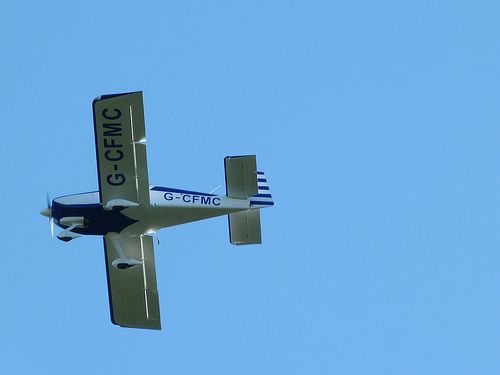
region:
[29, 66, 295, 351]
An airplane flying through the air.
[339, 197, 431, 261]
the sky is bright blue.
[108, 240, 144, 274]
The left landing gear of the plane.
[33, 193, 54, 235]
The propeller of the plane.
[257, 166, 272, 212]
The striped rudder of the plane.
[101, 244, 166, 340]
The left wing of the plane.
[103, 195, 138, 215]
The right landing gear of the plane.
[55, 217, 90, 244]
The front landing gear of the plane.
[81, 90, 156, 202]
The other wing of the plane.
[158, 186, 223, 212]
G-CFMC written in blue on the tail of the plane.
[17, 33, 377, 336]
an airplane flying across the sky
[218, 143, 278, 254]
the tail of an airplane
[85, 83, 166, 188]
the wing of an airplane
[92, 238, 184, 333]
the wing of an airplane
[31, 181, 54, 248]
the propeller of an airplane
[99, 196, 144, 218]
the landing gear of an airplane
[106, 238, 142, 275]
the landing gear of an airplane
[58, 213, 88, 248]
the landing gear of an airplane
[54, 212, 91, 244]
the nose gear of an airplane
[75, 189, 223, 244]
the fuselage of an airplane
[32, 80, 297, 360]
plane in the sky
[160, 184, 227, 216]
g-cfmc logo on the side of the plane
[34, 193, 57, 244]
propeller on the front of the plane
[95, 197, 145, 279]
landing gear on the plane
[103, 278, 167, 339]
wing on the plane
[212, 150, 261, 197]
back wing of the plane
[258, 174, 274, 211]
blue and white stripes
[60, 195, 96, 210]
white on the plane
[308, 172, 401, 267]
clear blue sunny sky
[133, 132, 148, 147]
light on the plane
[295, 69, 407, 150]
cloudless blue color in the sky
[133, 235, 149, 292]
white line under plane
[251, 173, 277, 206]
blue stripes on plane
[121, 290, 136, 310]
green color on plane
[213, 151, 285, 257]
tail of the plane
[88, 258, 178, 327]
side wings on the plane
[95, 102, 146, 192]
large blue words at bottom of plane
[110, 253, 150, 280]
small blue design on plane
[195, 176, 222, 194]
thin white pole on plane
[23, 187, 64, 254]
white propeller on front of plane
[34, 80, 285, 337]
a plane in the air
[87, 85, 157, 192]
left wing of plane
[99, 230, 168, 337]
right wing of plane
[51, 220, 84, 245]
front wheel of plane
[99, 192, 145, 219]
left wheel of plane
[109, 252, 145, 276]
right wheel of plane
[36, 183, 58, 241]
a propeller in front a plane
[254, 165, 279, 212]
a vertical stabilizer of plane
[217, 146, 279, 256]
the tail of plane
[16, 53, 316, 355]
plane traveling on a blue sky